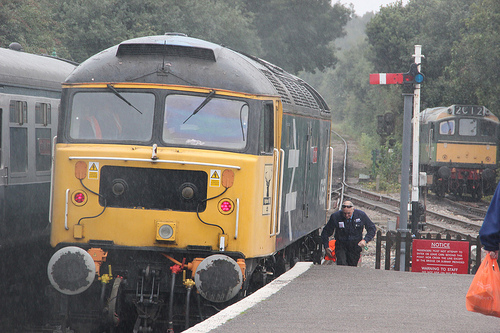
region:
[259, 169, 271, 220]
edge of a train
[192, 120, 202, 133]
window of a train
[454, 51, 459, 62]
part of a bush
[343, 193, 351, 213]
head of a man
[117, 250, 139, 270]
front of a train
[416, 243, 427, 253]
part of a notice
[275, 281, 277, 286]
edge of a slab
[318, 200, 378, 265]
A man in a black jacket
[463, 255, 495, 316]
An orange plastic bag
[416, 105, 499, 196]
A yellow and green train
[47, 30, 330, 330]
A yellow and green train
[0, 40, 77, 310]
A silver and green train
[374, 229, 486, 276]
A wooden fence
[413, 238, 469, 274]
A red sign on the fence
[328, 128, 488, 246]
A set of railroad tracks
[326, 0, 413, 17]
A cloudy sky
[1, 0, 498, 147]
A large wooded area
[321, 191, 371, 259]
A man walking on the train tracks.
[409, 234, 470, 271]
A notice warning sign in red.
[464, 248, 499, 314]
An orange shopping bag.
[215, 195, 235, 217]
The LED light on the train on the right.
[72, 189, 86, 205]
The left red LED light on the train.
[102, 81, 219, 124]
A pair of windshield wipers on the closest train.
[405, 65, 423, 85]
A pair of red and green signal lights.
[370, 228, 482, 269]
A brown, wood picket fence piece.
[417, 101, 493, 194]
A train identified as 2C12.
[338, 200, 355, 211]
The sunglasses on the man walking on the tracks.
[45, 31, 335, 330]
train pulling up to loading platform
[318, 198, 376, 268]
man walking up stairs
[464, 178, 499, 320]
person holding an orange bag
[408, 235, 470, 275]
red notice sign with white lettering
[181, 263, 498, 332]
section of loading platform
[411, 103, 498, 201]
train moving away from station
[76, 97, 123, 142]
driver of train through window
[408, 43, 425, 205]
a tall white post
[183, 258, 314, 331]
white line on edge of platform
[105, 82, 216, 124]
windshield wipers over window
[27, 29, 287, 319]
The front of a train.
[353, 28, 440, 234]
a white pole near train tracks.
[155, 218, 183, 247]
a train headlight.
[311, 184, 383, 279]
a man walking up steps.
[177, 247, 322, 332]
a white line near a train.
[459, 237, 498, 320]
An orange safety structure.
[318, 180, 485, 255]
train tracks behind a train.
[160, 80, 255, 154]
a windshield on a train.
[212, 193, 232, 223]
a left red light.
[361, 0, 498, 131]
a tree filled with green leaves.